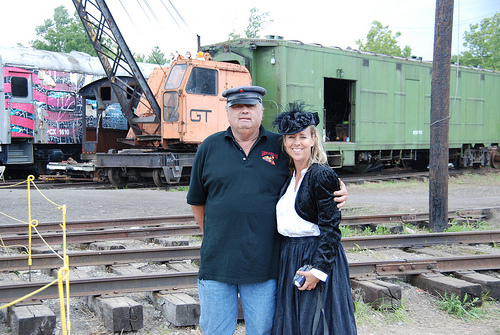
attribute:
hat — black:
[273, 87, 330, 139]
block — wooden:
[410, 272, 482, 307]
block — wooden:
[347, 277, 401, 312]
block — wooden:
[147, 290, 198, 327]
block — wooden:
[80, 292, 141, 333]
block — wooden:
[10, 298, 57, 333]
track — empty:
[2, 225, 499, 287]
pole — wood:
[428, 1, 453, 231]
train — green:
[398, 98, 419, 133]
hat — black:
[272, 102, 319, 135]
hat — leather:
[201, 81, 266, 106]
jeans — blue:
[193, 273, 274, 333]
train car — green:
[269, 41, 434, 139]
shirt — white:
[268, 166, 324, 236]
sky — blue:
[0, 0, 497, 74]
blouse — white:
[275, 167, 322, 235]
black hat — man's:
[218, 82, 268, 109]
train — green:
[95, 36, 493, 157]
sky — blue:
[212, 2, 258, 29]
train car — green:
[238, 36, 497, 159]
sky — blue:
[110, 2, 498, 56]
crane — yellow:
[74, 0, 254, 185]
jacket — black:
[269, 162, 345, 272]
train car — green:
[201, 25, 498, 180]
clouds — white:
[0, 1, 474, 60]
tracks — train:
[24, 170, 494, 301]